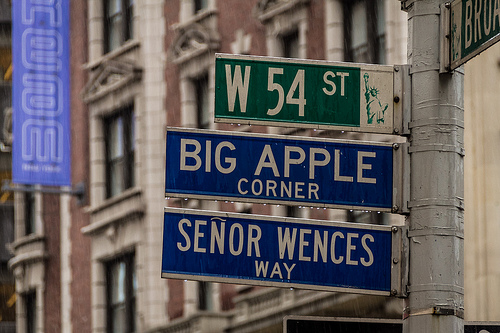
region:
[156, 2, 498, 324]
A post with street signs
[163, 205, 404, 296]
a blue street sign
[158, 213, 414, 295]
blue street sign with white font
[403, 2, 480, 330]
the metal pole of the street sign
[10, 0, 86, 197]
a blue banner in the air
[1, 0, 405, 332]
a brick building in the background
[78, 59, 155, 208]
a window of the building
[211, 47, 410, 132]
a green street sign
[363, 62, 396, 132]
the statue of liberty on the sign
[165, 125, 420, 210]
the sign says big apple corner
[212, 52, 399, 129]
Green and white street sign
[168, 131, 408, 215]
blue and white street sign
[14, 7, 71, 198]
blue and white banner on building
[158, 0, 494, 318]
street signs on metal pole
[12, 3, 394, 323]
building with many windows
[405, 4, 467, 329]
a rough silver metal pole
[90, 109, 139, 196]
window of tan and red building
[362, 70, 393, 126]
a drawing of the Statue of Liberty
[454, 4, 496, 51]
part of Broadway Street Sign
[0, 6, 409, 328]
tan and red building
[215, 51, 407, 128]
Green sign on pole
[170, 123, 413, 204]
Blue sign on pole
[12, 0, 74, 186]
Blue hanging banner near street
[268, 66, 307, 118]
White number on green sign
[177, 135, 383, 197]
White letters on blue sign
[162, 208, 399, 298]
Lowest blue sign on pole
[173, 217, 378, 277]
White letters on blue sign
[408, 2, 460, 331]
Metal pole with signs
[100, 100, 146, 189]
Window in tall building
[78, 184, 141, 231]
Window ledge on tall building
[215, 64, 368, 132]
sign for w 54th st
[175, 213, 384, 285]
sign for senor wences way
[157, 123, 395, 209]
sign for big apple corner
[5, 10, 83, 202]
the banner is hanging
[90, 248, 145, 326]
windows on the building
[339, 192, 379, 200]
the sign is blue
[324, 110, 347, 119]
the sign is green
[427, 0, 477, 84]
sign on the pole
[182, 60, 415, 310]
signs on the pole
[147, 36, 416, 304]
The signs on the pole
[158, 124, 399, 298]
The color of the signs are blue and white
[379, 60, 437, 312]
The hooks holding the signs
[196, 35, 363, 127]
The sign is green and white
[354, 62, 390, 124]
The picture of the Eiffel tower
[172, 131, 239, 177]
The word says "Big"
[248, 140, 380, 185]
The word says "Apple"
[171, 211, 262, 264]
The word says "Senor"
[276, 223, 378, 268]
The word says "Wences"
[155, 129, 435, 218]
a sign that is blue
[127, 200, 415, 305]
a sign that is large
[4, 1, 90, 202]
a sign that is hanging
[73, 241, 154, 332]
a window that is black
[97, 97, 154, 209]
a window that is rectangular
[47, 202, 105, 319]
a wall that is brick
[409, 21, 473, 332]
a pole that is thick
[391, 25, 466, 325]
a pole that is grey